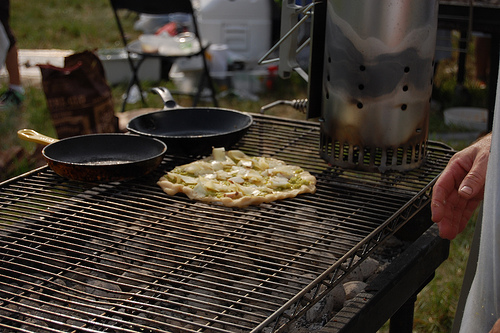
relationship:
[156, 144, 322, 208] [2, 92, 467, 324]
food on grill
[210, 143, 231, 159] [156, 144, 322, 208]
chicken on food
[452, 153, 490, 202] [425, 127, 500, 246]
thumb on right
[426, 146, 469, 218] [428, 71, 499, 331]
finger of person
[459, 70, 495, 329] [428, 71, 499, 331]
shirt on person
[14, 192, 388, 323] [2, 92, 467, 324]
charcoal in grill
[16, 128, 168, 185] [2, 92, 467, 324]
dish on grill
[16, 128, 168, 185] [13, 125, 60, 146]
dish with handle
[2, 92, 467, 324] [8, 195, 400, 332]
grill with coals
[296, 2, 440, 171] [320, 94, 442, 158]
furnace with marks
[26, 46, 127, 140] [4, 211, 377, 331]
bag of coal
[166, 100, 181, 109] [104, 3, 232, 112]
black picnic chair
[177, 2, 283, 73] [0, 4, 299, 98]
cooler in distance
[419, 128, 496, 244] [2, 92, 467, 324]
hand near grill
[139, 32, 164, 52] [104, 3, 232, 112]
containers on chair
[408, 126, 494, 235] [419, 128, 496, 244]
man's right hand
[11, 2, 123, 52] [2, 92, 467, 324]
grass on ground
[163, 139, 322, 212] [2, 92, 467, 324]
food on grill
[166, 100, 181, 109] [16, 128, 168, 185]
black frying dish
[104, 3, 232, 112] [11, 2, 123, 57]
chair in back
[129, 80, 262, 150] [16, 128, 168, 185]
light colored dish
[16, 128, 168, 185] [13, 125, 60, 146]
dish dark handle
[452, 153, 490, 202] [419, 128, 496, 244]
thumb on hand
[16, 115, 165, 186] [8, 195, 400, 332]
dish over coals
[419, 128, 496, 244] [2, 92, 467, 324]
hand behind grill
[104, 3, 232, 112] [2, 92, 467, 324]
chair behind grill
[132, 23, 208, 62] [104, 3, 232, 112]
containers on chair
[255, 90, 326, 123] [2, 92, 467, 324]
metal on grill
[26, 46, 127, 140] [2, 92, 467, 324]
bag behind grill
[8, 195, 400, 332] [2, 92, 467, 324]
coals under grill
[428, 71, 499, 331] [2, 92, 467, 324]
person beside grill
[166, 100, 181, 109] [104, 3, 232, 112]
black folding chair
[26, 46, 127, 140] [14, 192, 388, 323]
bag of charcoal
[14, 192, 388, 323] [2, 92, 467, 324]
charcoal underneath grill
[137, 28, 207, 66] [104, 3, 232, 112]
stuff on chair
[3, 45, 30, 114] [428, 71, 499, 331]
leg of person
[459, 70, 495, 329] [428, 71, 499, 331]
shirt of person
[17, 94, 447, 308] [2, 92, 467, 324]
grate on grill